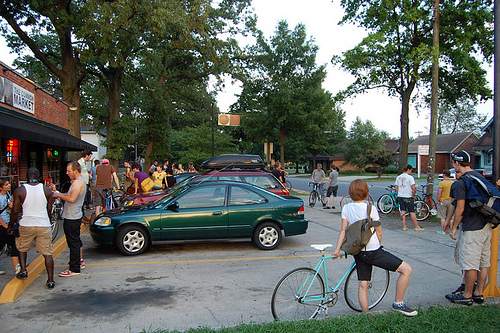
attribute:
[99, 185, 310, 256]
car — green, parked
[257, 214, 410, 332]
bike — blue, parked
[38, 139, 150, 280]
people — sitting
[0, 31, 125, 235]
store — here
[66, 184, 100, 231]
shirt — grey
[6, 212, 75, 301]
curb — yellow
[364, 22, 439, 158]
tree — green, big, here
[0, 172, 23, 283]
lady — standing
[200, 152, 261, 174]
carrier — large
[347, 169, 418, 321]
person — leaning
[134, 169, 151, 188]
shirt — purple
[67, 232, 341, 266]
spot — here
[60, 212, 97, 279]
pants — black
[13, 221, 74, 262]
shorts — khaki, black, here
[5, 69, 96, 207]
market — here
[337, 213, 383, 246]
bag — brown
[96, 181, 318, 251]
sedan — green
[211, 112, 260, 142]
flag — small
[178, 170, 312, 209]
car — red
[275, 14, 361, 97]
sky — clear